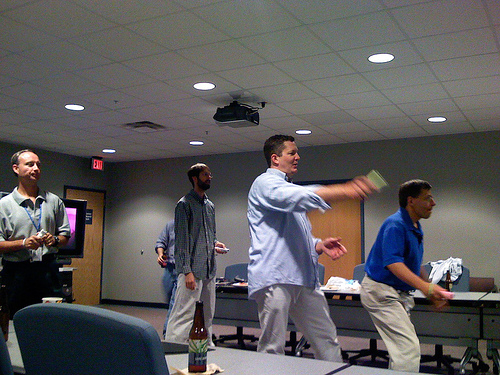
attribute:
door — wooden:
[60, 187, 106, 304]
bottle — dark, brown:
[153, 281, 245, 368]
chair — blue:
[12, 300, 172, 372]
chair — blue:
[220, 260, 250, 281]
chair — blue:
[312, 259, 326, 286]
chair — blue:
[347, 260, 371, 284]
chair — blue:
[450, 265, 472, 290]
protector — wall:
[137, 249, 147, 258]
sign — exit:
[88, 160, 103, 170]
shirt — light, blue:
[261, 178, 331, 273]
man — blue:
[376, 202, 446, 282]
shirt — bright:
[365, 208, 425, 291]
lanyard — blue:
[21, 197, 47, 251]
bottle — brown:
[186, 295, 211, 373]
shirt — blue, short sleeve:
[363, 205, 422, 292]